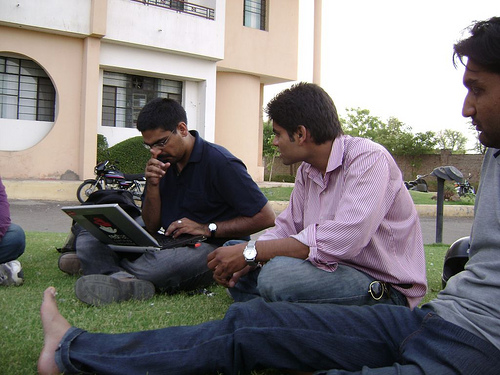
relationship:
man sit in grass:
[54, 90, 275, 308] [7, 282, 213, 323]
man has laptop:
[54, 90, 275, 308] [57, 200, 199, 257]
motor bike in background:
[73, 157, 145, 202] [2, 168, 147, 185]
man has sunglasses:
[54, 90, 275, 308] [139, 138, 174, 152]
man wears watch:
[205, 77, 435, 300] [241, 235, 262, 265]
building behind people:
[1, 2, 302, 104] [5, 21, 500, 374]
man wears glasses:
[54, 90, 275, 308] [139, 138, 174, 152]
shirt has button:
[246, 140, 430, 297] [319, 189, 330, 197]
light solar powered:
[423, 155, 467, 242] [427, 162, 467, 189]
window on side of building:
[3, 55, 61, 154] [1, 2, 302, 104]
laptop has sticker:
[57, 200, 199, 257] [81, 211, 127, 242]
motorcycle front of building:
[73, 157, 145, 202] [1, 2, 302, 104]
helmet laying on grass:
[437, 232, 472, 281] [427, 246, 442, 296]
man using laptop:
[54, 90, 275, 308] [57, 200, 199, 257]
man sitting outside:
[54, 90, 275, 308] [5, 30, 500, 372]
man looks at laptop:
[54, 90, 275, 308] [57, 200, 199, 257]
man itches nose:
[54, 90, 275, 308] [150, 141, 161, 159]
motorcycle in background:
[73, 157, 145, 202] [2, 168, 147, 185]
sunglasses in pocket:
[365, 275, 395, 302] [356, 277, 401, 307]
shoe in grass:
[73, 268, 159, 305] [7, 282, 213, 323]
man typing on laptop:
[54, 90, 275, 308] [57, 200, 199, 257]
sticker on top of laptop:
[81, 211, 127, 242] [57, 200, 199, 257]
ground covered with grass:
[24, 236, 118, 325] [24, 234, 81, 303]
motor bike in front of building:
[73, 157, 145, 202] [1, 2, 302, 104]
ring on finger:
[175, 218, 184, 227] [165, 215, 187, 228]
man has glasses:
[54, 90, 275, 308] [139, 138, 174, 152]